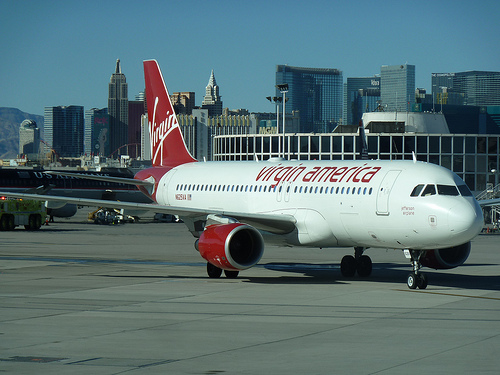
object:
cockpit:
[409, 183, 477, 216]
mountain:
[0, 103, 43, 157]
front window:
[409, 183, 474, 197]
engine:
[198, 222, 266, 270]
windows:
[238, 136, 413, 161]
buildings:
[41, 104, 110, 158]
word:
[300, 160, 381, 186]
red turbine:
[198, 222, 266, 271]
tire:
[28, 213, 43, 229]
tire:
[1, 213, 15, 231]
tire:
[206, 261, 239, 278]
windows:
[173, 184, 374, 196]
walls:
[194, 132, 496, 167]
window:
[410, 183, 425, 197]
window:
[437, 184, 459, 197]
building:
[107, 57, 130, 160]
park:
[5, 54, 490, 295]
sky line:
[235, 34, 500, 64]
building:
[200, 66, 224, 117]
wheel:
[407, 273, 429, 289]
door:
[372, 160, 410, 236]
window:
[175, 183, 183, 190]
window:
[184, 183, 196, 191]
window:
[197, 184, 209, 191]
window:
[209, 184, 222, 191]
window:
[240, 184, 254, 193]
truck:
[1, 196, 48, 231]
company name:
[256, 162, 382, 188]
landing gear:
[340, 247, 372, 278]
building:
[206, 128, 499, 197]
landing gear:
[402, 248, 431, 289]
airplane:
[0, 57, 485, 290]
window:
[421, 184, 437, 198]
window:
[294, 186, 298, 194]